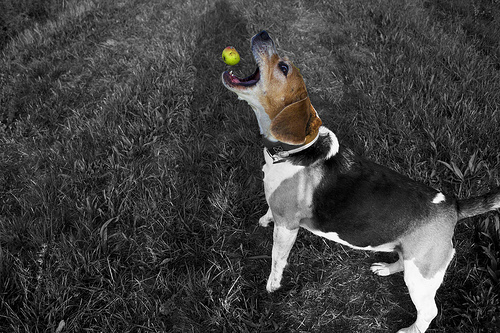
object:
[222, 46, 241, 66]
fruit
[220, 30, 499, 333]
dog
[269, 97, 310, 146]
ear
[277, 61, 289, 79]
eye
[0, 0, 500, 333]
grass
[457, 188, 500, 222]
tail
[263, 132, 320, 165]
collar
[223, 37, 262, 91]
mouth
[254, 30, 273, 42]
nose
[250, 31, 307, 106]
face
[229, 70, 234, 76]
tooth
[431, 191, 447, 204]
spot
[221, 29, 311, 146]
head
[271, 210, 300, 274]
front leg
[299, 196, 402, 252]
belly